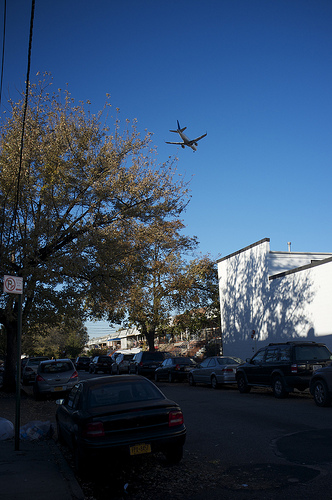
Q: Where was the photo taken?
A: It was taken at the city.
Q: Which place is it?
A: It is a city.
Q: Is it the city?
A: Yes, it is the city.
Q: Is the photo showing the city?
A: Yes, it is showing the city.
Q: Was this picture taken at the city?
A: Yes, it was taken in the city.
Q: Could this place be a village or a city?
A: It is a city.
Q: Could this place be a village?
A: No, it is a city.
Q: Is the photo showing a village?
A: No, the picture is showing a city.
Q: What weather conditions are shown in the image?
A: It is clear.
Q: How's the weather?
A: It is clear.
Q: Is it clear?
A: Yes, it is clear.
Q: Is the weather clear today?
A: Yes, it is clear.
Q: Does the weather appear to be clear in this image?
A: Yes, it is clear.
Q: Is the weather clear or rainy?
A: It is clear.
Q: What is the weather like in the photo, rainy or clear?
A: It is clear.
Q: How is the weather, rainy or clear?
A: It is clear.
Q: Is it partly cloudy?
A: No, it is clear.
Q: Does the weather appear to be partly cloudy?
A: No, it is clear.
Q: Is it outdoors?
A: Yes, it is outdoors.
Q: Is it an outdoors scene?
A: Yes, it is outdoors.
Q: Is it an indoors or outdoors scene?
A: It is outdoors.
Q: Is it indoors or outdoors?
A: It is outdoors.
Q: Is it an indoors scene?
A: No, it is outdoors.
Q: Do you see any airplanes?
A: Yes, there is an airplane.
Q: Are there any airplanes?
A: Yes, there is an airplane.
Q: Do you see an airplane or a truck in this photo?
A: Yes, there is an airplane.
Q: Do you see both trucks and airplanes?
A: No, there is an airplane but no trucks.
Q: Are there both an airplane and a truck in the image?
A: No, there is an airplane but no trucks.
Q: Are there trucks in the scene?
A: No, there are no trucks.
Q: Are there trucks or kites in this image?
A: No, there are no trucks or kites.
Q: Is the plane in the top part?
A: Yes, the plane is in the top of the image.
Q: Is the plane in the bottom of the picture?
A: No, the plane is in the top of the image.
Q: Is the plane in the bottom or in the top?
A: The plane is in the top of the image.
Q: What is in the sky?
A: The airplane is in the sky.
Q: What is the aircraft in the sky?
A: The aircraft is an airplane.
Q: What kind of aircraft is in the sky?
A: The aircraft is an airplane.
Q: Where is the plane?
A: The plane is in the sky.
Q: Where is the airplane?
A: The plane is in the sky.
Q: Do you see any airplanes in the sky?
A: Yes, there is an airplane in the sky.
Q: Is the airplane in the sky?
A: Yes, the airplane is in the sky.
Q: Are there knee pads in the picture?
A: No, there are no knee pads.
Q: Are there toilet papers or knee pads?
A: No, there are no knee pads or toilet papers.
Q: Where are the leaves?
A: The leaves are on the ground.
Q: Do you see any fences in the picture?
A: No, there are no fences.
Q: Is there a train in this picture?
A: No, there are no trains.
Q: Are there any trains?
A: No, there are no trains.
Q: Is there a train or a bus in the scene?
A: No, there are no trains or buses.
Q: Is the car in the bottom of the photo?
A: Yes, the car is in the bottom of the image.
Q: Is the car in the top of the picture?
A: No, the car is in the bottom of the image.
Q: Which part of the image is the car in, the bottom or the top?
A: The car is in the bottom of the image.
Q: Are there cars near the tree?
A: Yes, there is a car near the tree.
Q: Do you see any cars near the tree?
A: Yes, there is a car near the tree.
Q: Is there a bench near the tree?
A: No, there is a car near the tree.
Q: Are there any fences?
A: No, there are no fences.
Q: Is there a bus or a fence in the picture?
A: No, there are no fences or buses.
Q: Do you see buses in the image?
A: No, there are no buses.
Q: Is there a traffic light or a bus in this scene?
A: No, there are no buses or traffic lights.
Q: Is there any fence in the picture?
A: No, there are no fences.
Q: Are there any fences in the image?
A: No, there are no fences.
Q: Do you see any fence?
A: No, there are no fences.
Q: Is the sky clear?
A: Yes, the sky is clear.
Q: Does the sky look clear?
A: Yes, the sky is clear.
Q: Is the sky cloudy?
A: No, the sky is clear.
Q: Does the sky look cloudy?
A: No, the sky is clear.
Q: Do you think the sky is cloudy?
A: No, the sky is clear.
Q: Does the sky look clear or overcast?
A: The sky is clear.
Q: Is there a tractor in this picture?
A: No, there are no tractors.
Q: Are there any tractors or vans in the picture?
A: No, there are no tractors or vans.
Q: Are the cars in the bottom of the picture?
A: Yes, the cars are in the bottom of the image.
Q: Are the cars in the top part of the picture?
A: No, the cars are in the bottom of the image.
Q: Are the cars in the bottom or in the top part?
A: The cars are in the bottom of the image.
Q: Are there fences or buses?
A: No, there are no fences or buses.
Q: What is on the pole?
A: The sign is on the pole.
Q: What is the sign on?
A: The sign is on the pole.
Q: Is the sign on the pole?
A: Yes, the sign is on the pole.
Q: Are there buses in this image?
A: No, there are no buses.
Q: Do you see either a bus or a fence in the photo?
A: No, there are no buses or fences.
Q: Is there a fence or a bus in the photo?
A: No, there are no buses or fences.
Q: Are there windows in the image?
A: Yes, there are windows.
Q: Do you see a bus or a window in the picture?
A: Yes, there are windows.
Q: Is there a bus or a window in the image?
A: Yes, there are windows.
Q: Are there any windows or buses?
A: Yes, there are windows.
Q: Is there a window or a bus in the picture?
A: Yes, there are windows.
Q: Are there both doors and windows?
A: No, there are windows but no doors.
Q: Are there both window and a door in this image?
A: No, there are windows but no doors.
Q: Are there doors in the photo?
A: No, there are no doors.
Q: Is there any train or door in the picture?
A: No, there are no doors or trains.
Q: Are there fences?
A: No, there are no fences.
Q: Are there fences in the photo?
A: No, there are no fences.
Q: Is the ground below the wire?
A: Yes, the ground is below the wire.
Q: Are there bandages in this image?
A: No, there are no bandages.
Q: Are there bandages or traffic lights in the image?
A: No, there are no bandages or traffic lights.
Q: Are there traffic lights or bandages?
A: No, there are no bandages or traffic lights.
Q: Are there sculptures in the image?
A: No, there are no sculptures.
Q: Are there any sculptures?
A: No, there are no sculptures.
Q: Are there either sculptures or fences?
A: No, there are no sculptures or fences.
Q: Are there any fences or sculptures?
A: No, there are no sculptures or fences.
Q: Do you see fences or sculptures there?
A: No, there are no sculptures or fences.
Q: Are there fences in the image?
A: No, there are no fences.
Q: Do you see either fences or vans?
A: No, there are no fences or vans.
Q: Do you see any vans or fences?
A: No, there are no fences or vans.